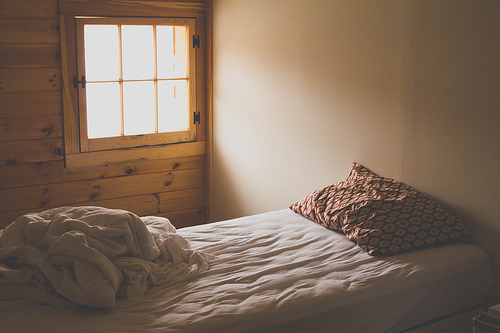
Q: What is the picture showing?
A: It is showing a bedroom.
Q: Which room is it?
A: It is a bedroom.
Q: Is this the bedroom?
A: Yes, it is the bedroom.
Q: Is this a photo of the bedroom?
A: Yes, it is showing the bedroom.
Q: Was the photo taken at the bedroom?
A: Yes, it was taken in the bedroom.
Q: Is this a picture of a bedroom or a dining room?
A: It is showing a bedroom.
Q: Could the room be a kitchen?
A: No, it is a bedroom.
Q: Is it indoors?
A: Yes, it is indoors.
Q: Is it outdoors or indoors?
A: It is indoors.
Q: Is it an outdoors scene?
A: No, it is indoors.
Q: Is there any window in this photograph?
A: Yes, there is a window.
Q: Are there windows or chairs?
A: Yes, there is a window.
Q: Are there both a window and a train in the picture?
A: No, there is a window but no trains.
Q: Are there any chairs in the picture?
A: No, there are no chairs.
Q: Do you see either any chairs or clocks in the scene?
A: No, there are no chairs or clocks.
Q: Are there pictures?
A: No, there are no pictures.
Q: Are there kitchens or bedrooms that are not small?
A: No, there is a bedroom but it is small.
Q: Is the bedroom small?
A: Yes, the bedroom is small.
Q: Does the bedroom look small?
A: Yes, the bedroom is small.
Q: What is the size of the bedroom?
A: The bedroom is small.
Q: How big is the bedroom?
A: The bedroom is small.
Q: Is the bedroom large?
A: No, the bedroom is small.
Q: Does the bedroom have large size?
A: No, the bedroom is small.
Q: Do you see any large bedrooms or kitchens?
A: No, there is a bedroom but it is small.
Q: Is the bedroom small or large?
A: The bedroom is small.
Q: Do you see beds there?
A: Yes, there is a bed.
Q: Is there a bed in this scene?
A: Yes, there is a bed.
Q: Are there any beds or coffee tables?
A: Yes, there is a bed.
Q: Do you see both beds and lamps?
A: No, there is a bed but no lamps.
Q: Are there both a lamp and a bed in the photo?
A: No, there is a bed but no lamps.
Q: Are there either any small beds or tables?
A: Yes, there is a small bed.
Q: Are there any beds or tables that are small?
A: Yes, the bed is small.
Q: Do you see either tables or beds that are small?
A: Yes, the bed is small.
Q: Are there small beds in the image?
A: Yes, there is a small bed.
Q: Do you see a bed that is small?
A: Yes, there is a bed that is small.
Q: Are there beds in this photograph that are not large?
A: Yes, there is a small bed.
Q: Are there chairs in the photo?
A: No, there are no chairs.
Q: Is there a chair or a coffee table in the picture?
A: No, there are no chairs or coffee tables.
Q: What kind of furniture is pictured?
A: The furniture is a bed.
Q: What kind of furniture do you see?
A: The furniture is a bed.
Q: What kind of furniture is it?
A: The piece of furniture is a bed.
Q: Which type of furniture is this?
A: That is a bed.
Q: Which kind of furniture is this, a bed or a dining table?
A: That is a bed.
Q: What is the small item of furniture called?
A: The piece of furniture is a bed.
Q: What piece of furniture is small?
A: The piece of furniture is a bed.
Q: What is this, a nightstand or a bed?
A: This is a bed.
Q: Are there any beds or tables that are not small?
A: No, there is a bed but it is small.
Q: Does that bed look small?
A: Yes, the bed is small.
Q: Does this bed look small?
A: Yes, the bed is small.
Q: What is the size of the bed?
A: The bed is small.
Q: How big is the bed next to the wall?
A: The bed is small.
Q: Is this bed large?
A: No, the bed is small.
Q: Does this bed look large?
A: No, the bed is small.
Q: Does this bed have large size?
A: No, the bed is small.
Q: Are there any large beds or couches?
A: No, there is a bed but it is small.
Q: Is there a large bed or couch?
A: No, there is a bed but it is small.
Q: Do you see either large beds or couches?
A: No, there is a bed but it is small.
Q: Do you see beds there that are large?
A: No, there is a bed but it is small.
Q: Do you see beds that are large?
A: No, there is a bed but it is small.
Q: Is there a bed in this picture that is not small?
A: No, there is a bed but it is small.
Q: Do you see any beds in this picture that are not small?
A: No, there is a bed but it is small.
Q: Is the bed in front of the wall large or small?
A: The bed is small.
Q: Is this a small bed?
A: Yes, this is a small bed.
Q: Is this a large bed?
A: No, this is a small bed.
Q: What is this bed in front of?
A: The bed is in front of the wall.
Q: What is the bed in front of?
A: The bed is in front of the wall.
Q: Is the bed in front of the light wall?
A: Yes, the bed is in front of the wall.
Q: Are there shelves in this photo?
A: No, there are no shelves.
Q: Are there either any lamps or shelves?
A: No, there are no shelves or lamps.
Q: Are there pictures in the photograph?
A: No, there are no pictures.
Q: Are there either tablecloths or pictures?
A: No, there are no pictures or tablecloths.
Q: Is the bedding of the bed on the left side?
A: Yes, the bedding is on the left of the image.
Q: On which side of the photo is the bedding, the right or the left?
A: The bedding is on the left of the image.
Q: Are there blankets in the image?
A: Yes, there is a blanket.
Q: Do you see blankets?
A: Yes, there is a blanket.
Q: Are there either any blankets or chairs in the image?
A: Yes, there is a blanket.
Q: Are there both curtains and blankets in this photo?
A: No, there is a blanket but no curtains.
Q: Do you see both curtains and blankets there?
A: No, there is a blanket but no curtains.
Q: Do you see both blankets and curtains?
A: No, there is a blanket but no curtains.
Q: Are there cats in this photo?
A: No, there are no cats.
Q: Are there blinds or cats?
A: No, there are no cats or blinds.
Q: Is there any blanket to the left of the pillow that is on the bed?
A: Yes, there is a blanket to the left of the pillow.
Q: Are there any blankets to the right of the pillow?
A: No, the blanket is to the left of the pillow.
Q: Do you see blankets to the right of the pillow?
A: No, the blanket is to the left of the pillow.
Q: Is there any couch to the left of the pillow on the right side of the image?
A: No, there is a blanket to the left of the pillow.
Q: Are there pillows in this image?
A: Yes, there is a pillow.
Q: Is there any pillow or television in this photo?
A: Yes, there is a pillow.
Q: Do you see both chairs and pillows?
A: No, there is a pillow but no chairs.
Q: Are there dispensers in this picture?
A: No, there are no dispensers.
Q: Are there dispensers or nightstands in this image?
A: No, there are no dispensers or nightstands.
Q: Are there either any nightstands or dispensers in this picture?
A: No, there are no dispensers or nightstands.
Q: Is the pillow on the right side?
A: Yes, the pillow is on the right of the image.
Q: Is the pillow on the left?
A: No, the pillow is on the right of the image.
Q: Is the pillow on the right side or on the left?
A: The pillow is on the right of the image.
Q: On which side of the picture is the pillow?
A: The pillow is on the right of the image.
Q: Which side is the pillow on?
A: The pillow is on the right of the image.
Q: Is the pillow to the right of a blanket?
A: Yes, the pillow is to the right of a blanket.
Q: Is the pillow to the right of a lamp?
A: No, the pillow is to the right of a blanket.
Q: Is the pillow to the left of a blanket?
A: No, the pillow is to the right of a blanket.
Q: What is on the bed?
A: The pillow is on the bed.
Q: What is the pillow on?
A: The pillow is on the bed.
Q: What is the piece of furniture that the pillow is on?
A: The piece of furniture is a bed.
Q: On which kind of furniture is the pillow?
A: The pillow is on the bed.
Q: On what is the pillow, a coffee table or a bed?
A: The pillow is on a bed.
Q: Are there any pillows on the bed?
A: Yes, there is a pillow on the bed.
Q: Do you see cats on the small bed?
A: No, there is a pillow on the bed.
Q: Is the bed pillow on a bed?
A: Yes, the pillow is on a bed.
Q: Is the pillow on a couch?
A: No, the pillow is on a bed.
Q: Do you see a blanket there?
A: Yes, there is a blanket.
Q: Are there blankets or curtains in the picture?
A: Yes, there is a blanket.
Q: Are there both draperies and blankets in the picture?
A: No, there is a blanket but no drapes.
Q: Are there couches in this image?
A: No, there are no couches.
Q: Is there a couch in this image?
A: No, there are no couches.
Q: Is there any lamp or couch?
A: No, there are no couches or lamps.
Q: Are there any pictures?
A: No, there are no pictures.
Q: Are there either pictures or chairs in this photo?
A: No, there are no pictures or chairs.